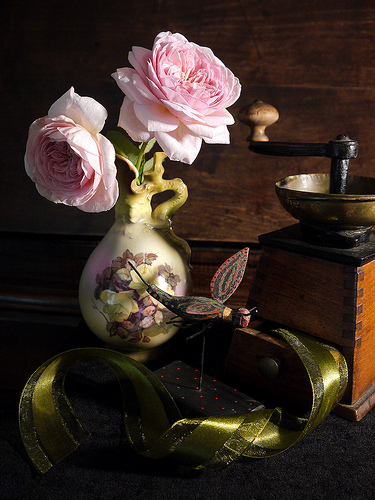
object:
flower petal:
[77, 177, 120, 212]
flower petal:
[117, 94, 153, 142]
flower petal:
[47, 86, 108, 137]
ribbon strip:
[17, 326, 348, 473]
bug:
[128, 245, 256, 340]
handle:
[151, 152, 187, 228]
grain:
[205, 167, 261, 229]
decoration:
[91, 248, 182, 342]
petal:
[83, 175, 119, 218]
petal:
[128, 41, 148, 72]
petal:
[110, 69, 144, 106]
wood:
[238, 100, 280, 143]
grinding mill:
[237, 99, 359, 196]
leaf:
[106, 131, 156, 185]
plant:
[24, 30, 242, 214]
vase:
[78, 152, 194, 359]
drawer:
[229, 325, 309, 394]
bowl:
[274, 172, 374, 227]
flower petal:
[133, 100, 178, 132]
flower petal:
[95, 133, 117, 190]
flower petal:
[154, 130, 201, 165]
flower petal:
[202, 125, 230, 144]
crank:
[250, 132, 359, 194]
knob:
[258, 359, 278, 381]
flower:
[23, 83, 120, 213]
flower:
[112, 30, 242, 167]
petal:
[57, 125, 99, 157]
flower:
[103, 292, 140, 323]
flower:
[128, 265, 158, 292]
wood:
[2, 74, 374, 243]